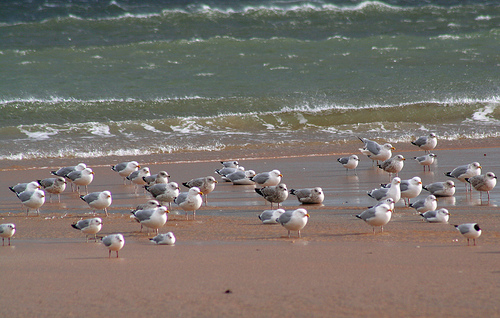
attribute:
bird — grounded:
[76, 181, 124, 219]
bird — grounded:
[352, 194, 399, 232]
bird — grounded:
[448, 216, 485, 246]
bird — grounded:
[142, 227, 179, 249]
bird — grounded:
[245, 163, 283, 188]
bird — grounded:
[331, 144, 365, 174]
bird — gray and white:
[463, 171, 498, 203]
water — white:
[1, 97, 386, 102]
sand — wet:
[0, 137, 499, 316]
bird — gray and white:
[66, 168, 94, 191]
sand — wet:
[209, 157, 481, 308]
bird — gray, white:
[15, 189, 45, 219]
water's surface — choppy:
[179, 50, 296, 87]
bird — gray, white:
[283, 206, 310, 243]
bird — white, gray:
[131, 201, 182, 249]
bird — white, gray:
[356, 196, 402, 238]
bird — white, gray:
[404, 130, 440, 153]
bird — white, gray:
[449, 213, 484, 240]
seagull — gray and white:
[241, 163, 283, 187]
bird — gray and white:
[180, 169, 218, 199]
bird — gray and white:
[347, 187, 409, 237]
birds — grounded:
[366, 176, 400, 213]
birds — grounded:
[355, 204, 392, 233]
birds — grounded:
[367, 197, 394, 212]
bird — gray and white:
[348, 140, 409, 179]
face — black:
[472, 220, 483, 232]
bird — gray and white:
[451, 219, 482, 248]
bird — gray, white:
[98, 232, 126, 258]